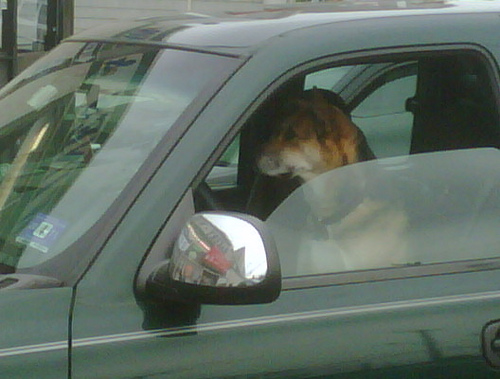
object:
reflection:
[176, 230, 236, 282]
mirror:
[157, 211, 282, 312]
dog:
[247, 85, 413, 276]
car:
[0, 8, 498, 378]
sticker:
[14, 212, 74, 256]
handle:
[479, 318, 499, 370]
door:
[71, 27, 499, 377]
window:
[265, 144, 498, 274]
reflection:
[285, 234, 340, 262]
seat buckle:
[397, 83, 438, 115]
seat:
[410, 97, 497, 254]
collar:
[300, 189, 377, 241]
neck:
[301, 165, 379, 226]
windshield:
[1, 43, 230, 272]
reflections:
[0, 52, 135, 212]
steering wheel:
[194, 175, 238, 218]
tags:
[310, 222, 333, 241]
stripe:
[0, 289, 498, 359]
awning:
[204, 243, 231, 276]